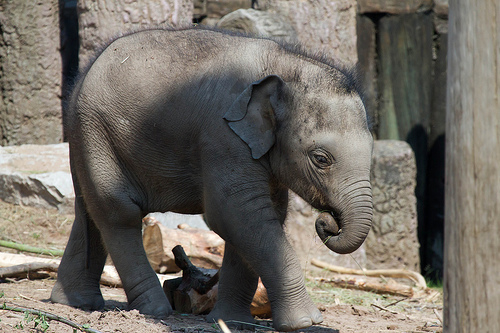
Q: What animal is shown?
A: An elephant.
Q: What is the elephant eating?
A: Hay.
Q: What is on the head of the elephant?
A: Hair.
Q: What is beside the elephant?
A: A pole.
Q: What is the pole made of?
A: Wood.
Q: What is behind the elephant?
A: A log.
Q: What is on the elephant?
A: A shadow.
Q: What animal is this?
A: An elephant.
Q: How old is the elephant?
A: Young.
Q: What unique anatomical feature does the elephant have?
A: A trunk.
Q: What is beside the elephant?
A: A pole.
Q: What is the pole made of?
A: Wood.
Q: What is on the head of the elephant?
A: Hair.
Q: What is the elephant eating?
A: Hay.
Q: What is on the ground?
A: Twigs.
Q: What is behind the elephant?
A: A log.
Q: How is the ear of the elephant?
A: Floppy.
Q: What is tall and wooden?
A: A pole.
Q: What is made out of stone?
A: A block.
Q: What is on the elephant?
A: A shadow.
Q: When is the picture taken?
A: Daytime.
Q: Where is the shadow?
A: In the ground.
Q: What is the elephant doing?
A: Walking.